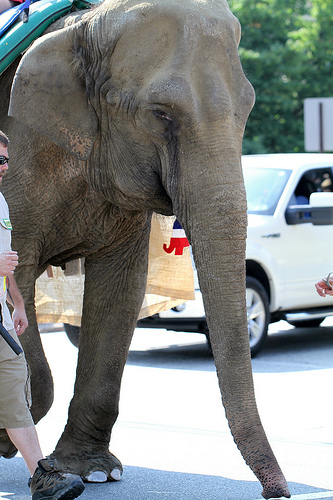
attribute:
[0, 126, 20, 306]
man — walking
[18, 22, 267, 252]
elephant — gray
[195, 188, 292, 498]
trunk — long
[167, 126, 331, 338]
car — parked, white